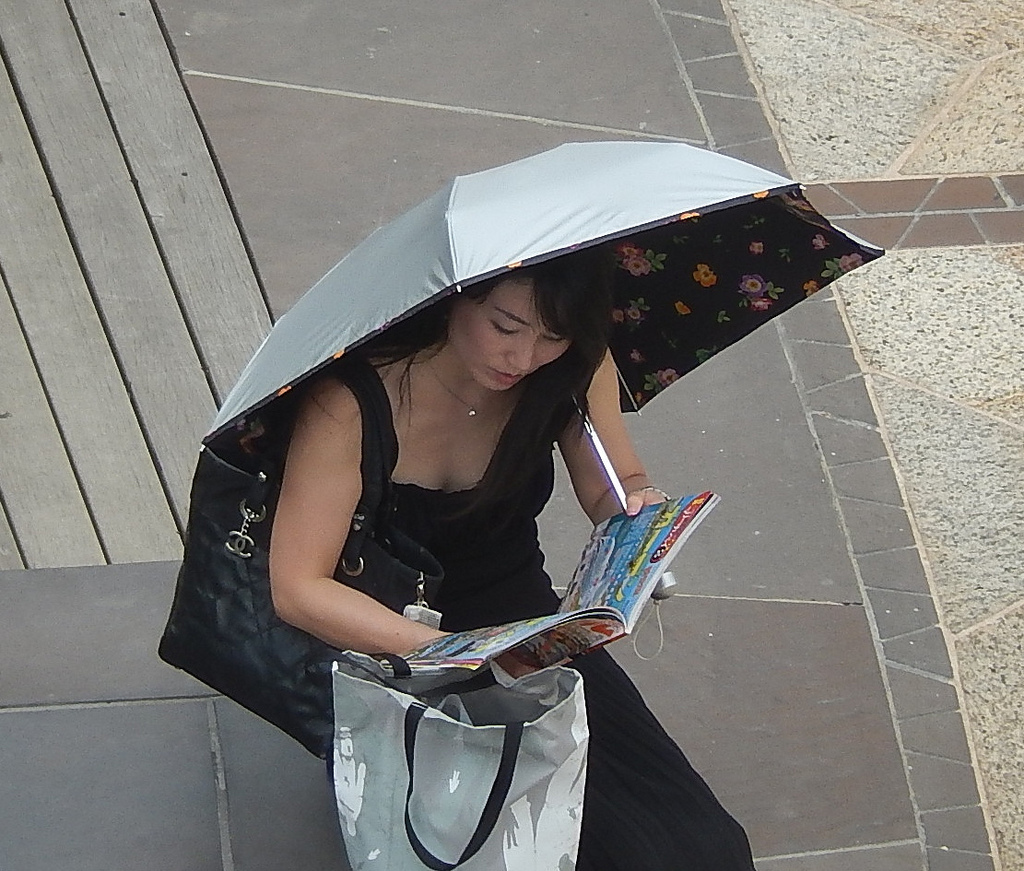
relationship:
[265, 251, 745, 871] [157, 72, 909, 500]
woman holding umbrella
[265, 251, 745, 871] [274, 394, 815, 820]
woman wearing dress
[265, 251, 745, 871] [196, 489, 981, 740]
woman reading magazine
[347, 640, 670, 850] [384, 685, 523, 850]
bag with handles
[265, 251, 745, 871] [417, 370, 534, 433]
woman wearing neacklace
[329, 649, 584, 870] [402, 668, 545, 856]
bag with strap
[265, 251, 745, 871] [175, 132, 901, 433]
woman under umbrella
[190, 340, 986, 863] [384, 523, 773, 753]
woman holding magazine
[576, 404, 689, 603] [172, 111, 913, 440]
pole for umbrella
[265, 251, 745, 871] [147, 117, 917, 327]
woman under umbrella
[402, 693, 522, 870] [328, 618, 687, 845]
handles on bag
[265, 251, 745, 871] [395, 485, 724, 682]
woman looking at magazine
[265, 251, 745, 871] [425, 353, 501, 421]
woman wearing necklace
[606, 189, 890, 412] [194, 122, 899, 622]
design on umbrella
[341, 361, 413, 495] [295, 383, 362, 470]
strap over shoulder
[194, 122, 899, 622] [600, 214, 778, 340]
umbrella with flowers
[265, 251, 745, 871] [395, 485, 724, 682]
woman holding magazine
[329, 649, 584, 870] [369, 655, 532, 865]
bag with handles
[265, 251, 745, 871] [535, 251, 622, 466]
woman has hair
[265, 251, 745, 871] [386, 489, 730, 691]
woman reading magazine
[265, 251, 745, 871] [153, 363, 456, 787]
woman holding bag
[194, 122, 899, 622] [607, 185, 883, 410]
umbrella covered with design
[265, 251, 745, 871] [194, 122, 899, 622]
woman holding umbrella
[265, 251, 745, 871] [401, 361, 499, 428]
woman wearing necklace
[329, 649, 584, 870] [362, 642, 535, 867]
bag with handles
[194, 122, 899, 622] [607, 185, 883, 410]
umbrella with design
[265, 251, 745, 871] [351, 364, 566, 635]
woman wearing shirt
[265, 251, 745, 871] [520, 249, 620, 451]
woman has hair